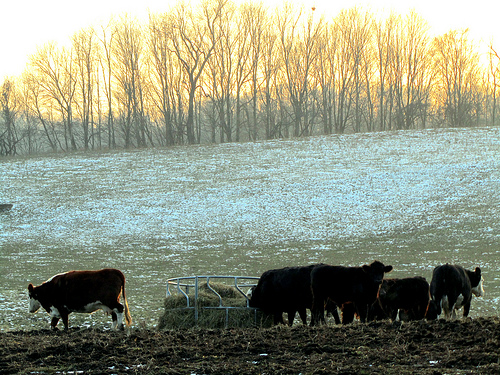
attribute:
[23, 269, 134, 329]
cow — brown, white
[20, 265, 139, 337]
cow — white, brown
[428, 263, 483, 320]
cow — black, white